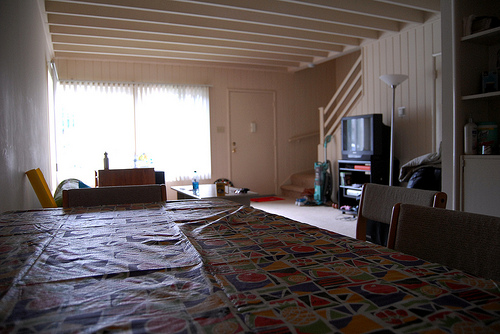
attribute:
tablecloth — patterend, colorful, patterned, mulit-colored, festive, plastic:
[3, 198, 498, 332]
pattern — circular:
[365, 282, 397, 294]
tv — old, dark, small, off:
[342, 112, 390, 158]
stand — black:
[335, 160, 398, 209]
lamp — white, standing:
[380, 73, 409, 185]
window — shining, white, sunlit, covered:
[59, 83, 210, 181]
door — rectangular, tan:
[230, 87, 276, 196]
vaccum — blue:
[313, 131, 331, 206]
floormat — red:
[251, 196, 283, 205]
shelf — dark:
[462, 92, 500, 99]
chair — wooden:
[388, 204, 499, 275]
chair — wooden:
[63, 186, 166, 206]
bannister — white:
[319, 55, 361, 141]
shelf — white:
[459, 26, 499, 41]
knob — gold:
[234, 151, 236, 155]